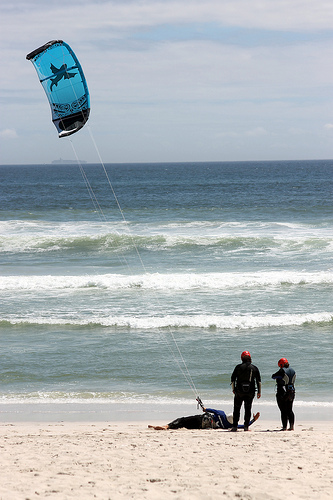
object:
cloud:
[0, 1, 331, 48]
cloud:
[89, 41, 332, 101]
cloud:
[105, 107, 329, 157]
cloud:
[0, 59, 46, 99]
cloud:
[0, 117, 53, 144]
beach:
[0, 404, 332, 498]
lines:
[66, 126, 163, 324]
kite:
[26, 38, 95, 137]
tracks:
[20, 437, 312, 497]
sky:
[122, 30, 275, 129]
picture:
[0, 0, 333, 500]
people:
[270, 356, 296, 432]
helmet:
[278, 357, 289, 367]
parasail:
[24, 38, 90, 143]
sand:
[171, 431, 259, 460]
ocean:
[179, 322, 324, 343]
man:
[230, 350, 261, 433]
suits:
[231, 362, 261, 427]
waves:
[0, 208, 329, 330]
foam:
[141, 314, 230, 328]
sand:
[2, 424, 71, 498]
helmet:
[241, 350, 252, 361]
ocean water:
[0, 160, 333, 392]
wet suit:
[272, 367, 298, 429]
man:
[148, 406, 261, 432]